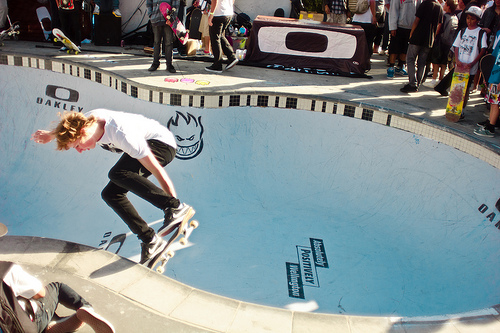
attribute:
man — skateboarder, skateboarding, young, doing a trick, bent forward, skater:
[31, 108, 191, 265]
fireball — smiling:
[164, 110, 205, 160]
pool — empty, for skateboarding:
[0, 54, 499, 316]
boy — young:
[448, 5, 489, 120]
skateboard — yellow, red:
[445, 62, 471, 125]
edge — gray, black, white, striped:
[1, 54, 499, 170]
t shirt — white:
[453, 25, 488, 75]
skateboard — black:
[147, 205, 200, 274]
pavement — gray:
[1, 38, 499, 151]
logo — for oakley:
[36, 84, 84, 116]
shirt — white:
[80, 108, 178, 161]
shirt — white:
[209, 0, 234, 19]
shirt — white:
[351, 7, 374, 23]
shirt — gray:
[388, 1, 418, 31]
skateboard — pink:
[157, 3, 189, 46]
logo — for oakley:
[95, 232, 127, 254]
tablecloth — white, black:
[246, 15, 369, 75]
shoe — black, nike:
[139, 236, 167, 262]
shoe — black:
[159, 202, 191, 230]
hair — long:
[52, 111, 96, 150]